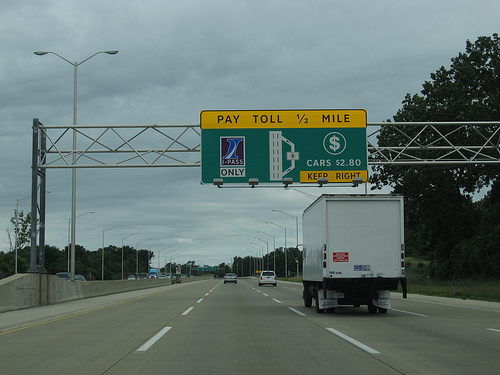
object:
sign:
[201, 109, 367, 183]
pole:
[37, 121, 500, 168]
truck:
[301, 194, 407, 314]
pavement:
[3, 277, 495, 372]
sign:
[333, 252, 349, 262]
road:
[5, 272, 495, 370]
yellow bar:
[200, 109, 368, 129]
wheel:
[316, 289, 335, 313]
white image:
[268, 131, 299, 181]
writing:
[252, 114, 283, 123]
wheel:
[302, 290, 311, 307]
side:
[59, 270, 194, 280]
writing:
[307, 159, 362, 167]